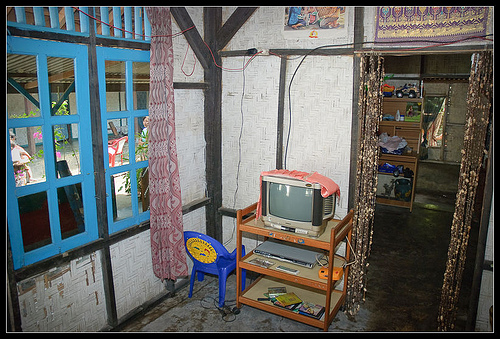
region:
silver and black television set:
[261, 174, 336, 237]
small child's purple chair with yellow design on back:
[176, 228, 246, 311]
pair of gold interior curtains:
[349, 51, 496, 329]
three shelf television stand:
[232, 204, 357, 333]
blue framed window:
[4, 7, 152, 271]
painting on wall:
[279, 6, 349, 34]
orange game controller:
[318, 259, 345, 281]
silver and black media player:
[251, 236, 325, 273]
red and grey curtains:
[146, 8, 191, 282]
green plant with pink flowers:
[11, 98, 76, 160]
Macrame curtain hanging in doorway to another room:
[440, 51, 498, 329]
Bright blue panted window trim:
[8, 33, 155, 262]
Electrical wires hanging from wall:
[228, 46, 303, 160]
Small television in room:
[265, 175, 320, 237]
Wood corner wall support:
[173, 10, 241, 237]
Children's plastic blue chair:
[183, 227, 243, 306]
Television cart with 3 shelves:
[231, 205, 346, 329]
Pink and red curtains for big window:
[146, 10, 188, 284]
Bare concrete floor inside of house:
[373, 210, 428, 328]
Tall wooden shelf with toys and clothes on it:
[375, 77, 420, 212]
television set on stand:
[234, 150, 356, 330]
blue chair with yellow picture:
[181, 218, 271, 323]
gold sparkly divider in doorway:
[336, 39, 496, 317]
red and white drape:
[124, 17, 258, 312]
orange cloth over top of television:
[230, 156, 380, 247]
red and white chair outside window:
[89, 110, 131, 175]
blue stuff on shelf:
[371, 139, 441, 193]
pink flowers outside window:
[24, 112, 82, 169]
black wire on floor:
[196, 290, 266, 332]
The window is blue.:
[10, 20, 150, 232]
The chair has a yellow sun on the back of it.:
[175, 211, 239, 306]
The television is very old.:
[256, 168, 338, 250]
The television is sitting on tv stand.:
[231, 178, 348, 336]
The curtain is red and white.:
[145, 77, 190, 273]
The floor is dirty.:
[392, 224, 439, 331]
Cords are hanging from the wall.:
[227, 75, 292, 180]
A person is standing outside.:
[13, 127, 37, 189]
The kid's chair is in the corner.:
[173, 198, 258, 306]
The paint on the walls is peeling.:
[16, 283, 122, 323]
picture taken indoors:
[44, 165, 494, 277]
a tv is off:
[219, 115, 367, 255]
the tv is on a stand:
[239, 148, 371, 272]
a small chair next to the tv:
[232, 172, 347, 334]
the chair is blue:
[192, 187, 247, 326]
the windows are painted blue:
[33, 147, 132, 234]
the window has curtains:
[110, 140, 210, 314]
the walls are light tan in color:
[197, 147, 327, 157]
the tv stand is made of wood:
[214, 219, 358, 331]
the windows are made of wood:
[50, 52, 172, 287]